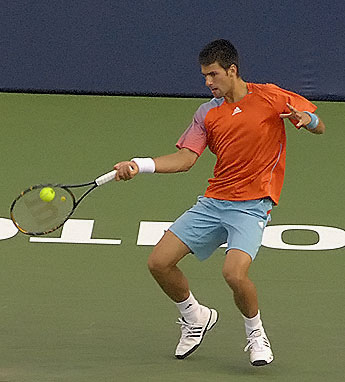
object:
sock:
[242, 309, 261, 327]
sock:
[175, 289, 201, 323]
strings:
[24, 188, 58, 226]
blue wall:
[0, 0, 344, 101]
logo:
[232, 106, 242, 116]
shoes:
[174, 305, 219, 359]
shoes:
[243, 319, 274, 366]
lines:
[186, 335, 200, 338]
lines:
[190, 327, 203, 330]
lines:
[188, 331, 202, 333]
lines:
[263, 344, 269, 348]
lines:
[263, 337, 267, 340]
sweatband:
[303, 111, 318, 130]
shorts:
[168, 196, 273, 262]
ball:
[39, 187, 56, 203]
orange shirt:
[176, 82, 317, 202]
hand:
[113, 161, 138, 182]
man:
[113, 39, 326, 367]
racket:
[10, 166, 134, 235]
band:
[130, 157, 155, 174]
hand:
[279, 102, 311, 128]